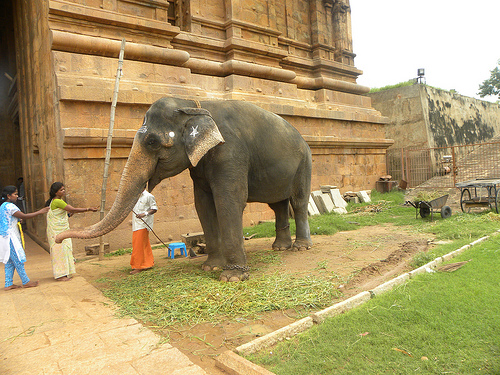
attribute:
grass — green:
[265, 249, 495, 368]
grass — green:
[325, 243, 482, 345]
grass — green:
[139, 240, 339, 349]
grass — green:
[107, 260, 265, 341]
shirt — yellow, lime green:
[44, 193, 84, 223]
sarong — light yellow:
[36, 190, 96, 260]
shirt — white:
[0, 191, 40, 252]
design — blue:
[0, 190, 40, 274]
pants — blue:
[0, 226, 42, 288]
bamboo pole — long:
[69, 0, 148, 281]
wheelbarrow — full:
[382, 160, 468, 244]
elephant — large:
[36, 85, 371, 296]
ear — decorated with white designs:
[165, 99, 228, 178]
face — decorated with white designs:
[109, 88, 193, 197]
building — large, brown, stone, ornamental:
[0, 0, 430, 299]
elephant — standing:
[33, 10, 468, 280]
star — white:
[185, 120, 215, 150]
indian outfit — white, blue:
[0, 144, 38, 300]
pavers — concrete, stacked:
[259, 163, 410, 256]